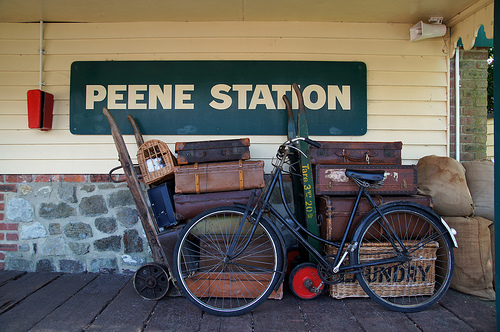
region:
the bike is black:
[161, 106, 467, 328]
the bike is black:
[150, 143, 465, 328]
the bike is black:
[193, 141, 426, 328]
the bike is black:
[153, 142, 433, 328]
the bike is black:
[159, 115, 490, 325]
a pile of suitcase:
[138, 129, 291, 319]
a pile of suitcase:
[131, 114, 283, 328]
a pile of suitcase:
[290, 129, 426, 329]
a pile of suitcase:
[149, 132, 283, 327]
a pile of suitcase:
[147, 129, 296, 325]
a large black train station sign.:
[69, 58, 374, 133]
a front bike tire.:
[166, 198, 289, 319]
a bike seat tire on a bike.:
[343, 161, 395, 196]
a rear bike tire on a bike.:
[344, 190, 464, 312]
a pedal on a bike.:
[287, 252, 341, 304]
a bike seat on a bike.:
[337, 157, 388, 204]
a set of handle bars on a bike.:
[266, 127, 326, 181]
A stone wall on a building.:
[0, 175, 161, 272]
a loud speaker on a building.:
[401, 7, 455, 44]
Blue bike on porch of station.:
[0, 134, 462, 329]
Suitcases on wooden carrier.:
[102, 105, 287, 308]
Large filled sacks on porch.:
[0, 154, 499, 329]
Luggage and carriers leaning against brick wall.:
[0, 172, 450, 288]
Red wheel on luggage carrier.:
[282, 83, 325, 299]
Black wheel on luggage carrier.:
[100, 103, 180, 305]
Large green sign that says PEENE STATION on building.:
[1, 44, 453, 184]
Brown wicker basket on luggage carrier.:
[97, 109, 184, 302]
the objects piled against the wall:
[101, 106, 498, 315]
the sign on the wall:
[69, 60, 367, 136]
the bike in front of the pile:
[173, 137, 457, 314]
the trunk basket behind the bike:
[329, 239, 439, 297]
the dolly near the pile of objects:
[102, 107, 180, 299]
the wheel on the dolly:
[130, 261, 169, 301]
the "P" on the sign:
[85, 84, 106, 108]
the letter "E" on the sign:
[107, 84, 126, 109]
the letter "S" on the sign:
[208, 83, 230, 108]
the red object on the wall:
[26, 89, 53, 129]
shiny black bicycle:
[165, 122, 465, 330]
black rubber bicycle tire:
[164, 199, 294, 316]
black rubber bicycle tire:
[344, 193, 459, 314]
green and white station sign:
[58, 53, 375, 140]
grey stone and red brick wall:
[0, 166, 167, 280]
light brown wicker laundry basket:
[322, 228, 436, 308]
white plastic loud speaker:
[404, 13, 451, 57]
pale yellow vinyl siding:
[0, 13, 461, 177]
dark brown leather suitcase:
[168, 136, 258, 166]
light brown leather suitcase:
[167, 155, 277, 196]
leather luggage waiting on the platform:
[171, 157, 267, 187]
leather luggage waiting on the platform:
[175, 135, 248, 163]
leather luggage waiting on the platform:
[307, 162, 417, 197]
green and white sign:
[68, 43, 375, 147]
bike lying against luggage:
[183, 161, 460, 317]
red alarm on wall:
[24, 88, 68, 157]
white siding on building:
[385, 54, 442, 139]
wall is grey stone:
[22, 204, 137, 276]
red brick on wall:
[0, 211, 34, 265]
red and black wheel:
[280, 257, 330, 299]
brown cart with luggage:
[110, 118, 187, 314]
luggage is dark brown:
[295, 96, 448, 268]